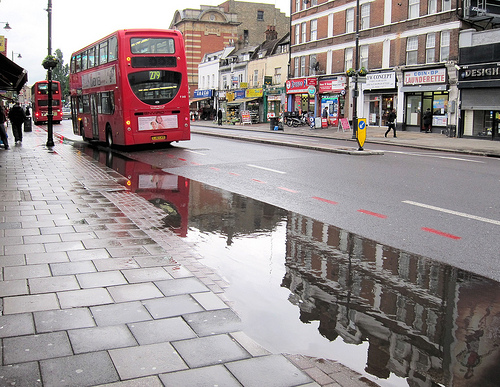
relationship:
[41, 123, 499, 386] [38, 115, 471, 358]
water puddle on side of right lane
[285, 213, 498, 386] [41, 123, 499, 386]
building reflected in water puddle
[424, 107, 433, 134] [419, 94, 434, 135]
person standing by door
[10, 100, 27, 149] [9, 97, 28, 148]
back of person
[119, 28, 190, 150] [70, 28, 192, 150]
back of bus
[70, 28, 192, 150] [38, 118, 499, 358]
bus driving in right lane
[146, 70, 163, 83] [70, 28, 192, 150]
279 number on front of bus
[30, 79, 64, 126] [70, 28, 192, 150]
bus behind front bus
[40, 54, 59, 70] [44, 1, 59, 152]
plant hanging on lamp post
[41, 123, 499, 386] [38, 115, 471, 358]
water puddle floating along right lane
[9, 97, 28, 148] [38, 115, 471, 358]
person walking on right lane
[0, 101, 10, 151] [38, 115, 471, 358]
person on top of right lane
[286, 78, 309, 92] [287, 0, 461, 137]
sign hanging on building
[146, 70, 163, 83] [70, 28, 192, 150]
279 number displayed on bus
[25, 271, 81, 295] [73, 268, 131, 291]
sidewalk brick next to another brick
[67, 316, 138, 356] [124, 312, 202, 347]
sidewalk brick next to another brick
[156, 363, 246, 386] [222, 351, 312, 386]
sidewalk brick next to another brick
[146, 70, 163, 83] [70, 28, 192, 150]
279 number shown on back of bus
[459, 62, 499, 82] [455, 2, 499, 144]
design written on building front